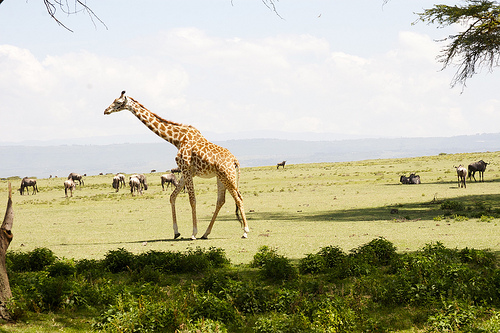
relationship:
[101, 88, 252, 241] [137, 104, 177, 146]
giraffe has neck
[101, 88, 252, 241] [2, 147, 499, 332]
giraffe in field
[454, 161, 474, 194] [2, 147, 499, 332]
animal in field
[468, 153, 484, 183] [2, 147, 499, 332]
animal in field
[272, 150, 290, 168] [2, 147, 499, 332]
animal in field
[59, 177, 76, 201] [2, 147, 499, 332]
animal in field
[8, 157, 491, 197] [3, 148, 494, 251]
animal herd in field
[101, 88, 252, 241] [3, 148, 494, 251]
giraffe in field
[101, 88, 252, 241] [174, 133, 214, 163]
giraffe has spots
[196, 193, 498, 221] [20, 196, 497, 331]
shadow on ground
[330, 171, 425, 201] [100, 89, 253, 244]
foothill behind animal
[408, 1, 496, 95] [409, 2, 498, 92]
tree has leaves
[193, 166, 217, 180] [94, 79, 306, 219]
stomach of a giraffe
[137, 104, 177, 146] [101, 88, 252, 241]
neck of giraffe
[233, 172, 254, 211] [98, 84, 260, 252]
tail of giraffe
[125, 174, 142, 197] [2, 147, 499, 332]
animal of field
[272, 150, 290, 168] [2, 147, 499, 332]
animal of field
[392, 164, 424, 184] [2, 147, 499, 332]
animal of field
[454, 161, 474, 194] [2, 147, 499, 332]
animal of field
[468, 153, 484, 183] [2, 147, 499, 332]
animal of field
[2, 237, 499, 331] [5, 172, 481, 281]
shrubs on side of field